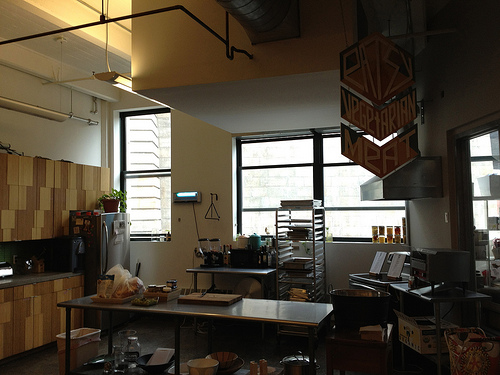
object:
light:
[90, 70, 174, 110]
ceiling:
[21, 0, 131, 54]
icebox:
[69, 210, 130, 333]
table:
[53, 293, 333, 375]